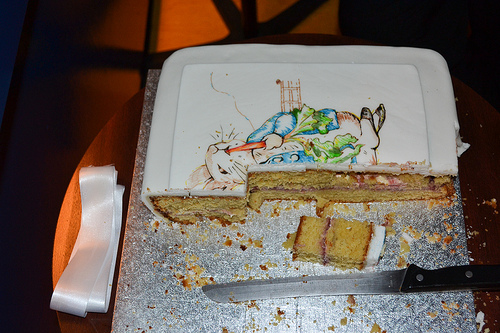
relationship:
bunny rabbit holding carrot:
[188, 102, 386, 191] [219, 140, 262, 151]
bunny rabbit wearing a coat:
[188, 102, 386, 191] [249, 110, 326, 163]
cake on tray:
[140, 40, 462, 227] [111, 65, 478, 331]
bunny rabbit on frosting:
[188, 102, 386, 191] [132, 43, 462, 199]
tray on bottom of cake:
[111, 201, 480, 331] [136, 37, 468, 260]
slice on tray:
[292, 215, 385, 270] [111, 65, 478, 331]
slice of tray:
[292, 215, 385, 270] [111, 65, 478, 331]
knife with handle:
[200, 262, 497, 302] [402, 261, 497, 290]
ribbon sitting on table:
[51, 153, 122, 317] [42, 32, 478, 331]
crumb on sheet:
[151, 221, 160, 229] [109, 65, 481, 331]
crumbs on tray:
[172, 252, 222, 288] [111, 65, 478, 331]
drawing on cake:
[189, 76, 394, 201] [136, 37, 468, 260]